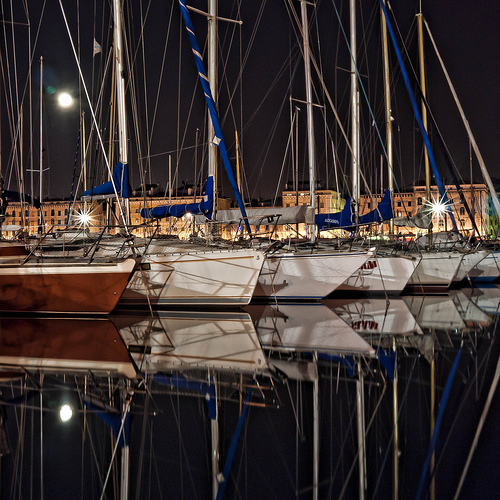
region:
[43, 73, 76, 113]
Moon and lens flare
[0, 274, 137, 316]
Brown bottom on boat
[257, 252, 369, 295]
White bottom on boat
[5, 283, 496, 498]
Reflection of boats on water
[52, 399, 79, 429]
Reflection of moon on water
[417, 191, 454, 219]
Bright light behind boat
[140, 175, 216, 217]
Blue sail on boat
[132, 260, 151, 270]
Small window on side of boat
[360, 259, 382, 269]
Letters on side of boat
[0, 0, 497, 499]
The boat docking area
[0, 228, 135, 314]
The brown boat on the right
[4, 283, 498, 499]
The boat reflecting water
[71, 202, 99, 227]
The bright light on the left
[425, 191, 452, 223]
The bright light on the right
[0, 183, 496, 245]
The background's brown buildings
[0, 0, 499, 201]
The dark sky background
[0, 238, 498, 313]
The lined up docked boats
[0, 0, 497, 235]
The tall boat stern posts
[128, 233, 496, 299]
The white boats on the right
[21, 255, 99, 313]
Brown boat docked in water.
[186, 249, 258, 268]
Brown stripe on boat.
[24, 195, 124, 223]
Large building behind boats.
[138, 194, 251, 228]
Large building behind boats.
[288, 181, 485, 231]
Large building behind boats.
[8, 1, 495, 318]
Row of moored sailboats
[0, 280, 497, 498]
Reflection of sailboats in water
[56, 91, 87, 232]
Illuminated light on pier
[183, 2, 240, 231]
Metal main mast of sailboat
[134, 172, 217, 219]
Folded and tied sail of boat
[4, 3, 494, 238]
Masts and support wires of boats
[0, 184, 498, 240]
Brick buildings along waters edge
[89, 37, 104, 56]
Pennat flag on sailboat mast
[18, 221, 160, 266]
Bow rail on sailboat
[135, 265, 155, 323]
Anchor line of sailboat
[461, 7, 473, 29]
the sky is black in color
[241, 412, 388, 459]
this is the water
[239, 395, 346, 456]
the water is still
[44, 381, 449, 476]
reflections of the boats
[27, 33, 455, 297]
these are the boats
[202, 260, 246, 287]
the boat is white in color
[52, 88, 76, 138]
this is the light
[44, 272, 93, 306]
the area is brown in color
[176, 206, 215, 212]
the cloth is blue in color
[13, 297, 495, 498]
The clear body of water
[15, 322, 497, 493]
A clear body of water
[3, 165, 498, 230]
A very dark sky